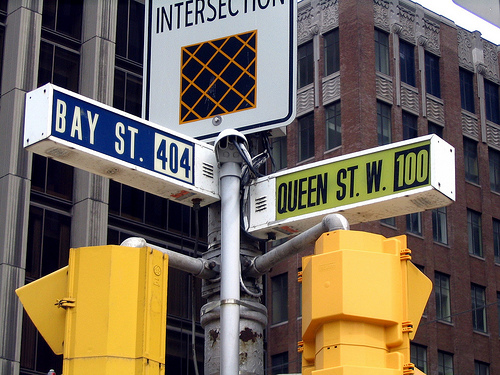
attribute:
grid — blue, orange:
[176, 25, 261, 127]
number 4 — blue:
[150, 130, 168, 186]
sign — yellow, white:
[140, 5, 293, 127]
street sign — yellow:
[243, 138, 449, 223]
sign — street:
[240, 145, 447, 207]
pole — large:
[182, 132, 261, 374]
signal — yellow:
[308, 203, 436, 372]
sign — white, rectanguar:
[247, 169, 438, 201]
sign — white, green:
[246, 132, 458, 241]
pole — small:
[211, 133, 264, 373]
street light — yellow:
[298, 229, 433, 374]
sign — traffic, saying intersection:
[142, 0, 298, 143]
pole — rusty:
[193, 233, 268, 370]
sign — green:
[238, 135, 489, 211]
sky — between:
[440, 0, 480, 32]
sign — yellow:
[243, 136, 433, 225]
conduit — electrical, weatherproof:
[213, 126, 259, 170]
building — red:
[296, 4, 483, 365]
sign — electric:
[21, 78, 223, 214]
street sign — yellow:
[242, 129, 464, 232]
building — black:
[1, 0, 213, 374]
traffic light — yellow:
[293, 227, 435, 374]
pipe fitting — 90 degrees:
[158, 121, 310, 311]